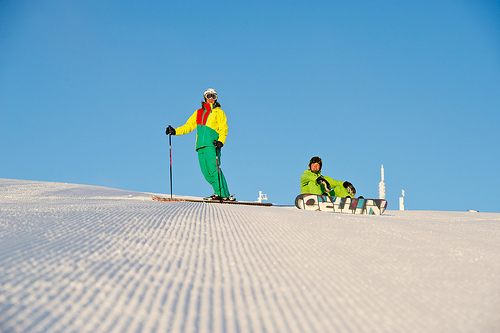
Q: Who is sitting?
A: Snowboarder.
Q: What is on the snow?
A: Lines.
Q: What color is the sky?
A: Blue.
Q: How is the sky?
A: Clear.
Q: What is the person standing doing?
A: Skiing.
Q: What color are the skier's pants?
A: Green.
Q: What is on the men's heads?
A: Helmets.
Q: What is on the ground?
A: Snow.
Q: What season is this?
A: Winter.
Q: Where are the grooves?
A: In the snow.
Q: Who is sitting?
A: The snowboarder.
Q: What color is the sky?
A: Blue.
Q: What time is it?
A: Afternoon.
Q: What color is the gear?
A: Yellow and green.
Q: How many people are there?
A: Two.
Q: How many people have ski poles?
A: One.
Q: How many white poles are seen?
A: Three.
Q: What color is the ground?
A: White.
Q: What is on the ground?
A: Snow.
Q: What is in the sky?
A: Nothing.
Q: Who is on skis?
A: A person.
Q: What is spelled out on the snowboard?
A: OELLIN.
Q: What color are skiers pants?
A: Green.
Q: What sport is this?
A: Sking.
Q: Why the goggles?
A: Protection.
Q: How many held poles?
A: Two.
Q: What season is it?
A: Winter.